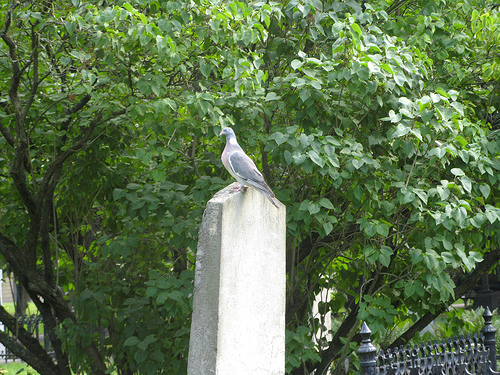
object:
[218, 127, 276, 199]
bird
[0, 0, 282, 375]
trees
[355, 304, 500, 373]
fence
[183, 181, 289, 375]
monument